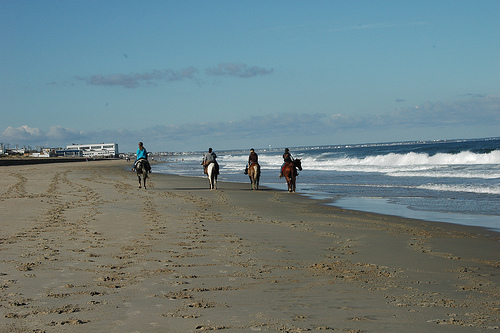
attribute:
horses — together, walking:
[130, 139, 309, 196]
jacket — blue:
[135, 145, 150, 161]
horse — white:
[201, 155, 221, 190]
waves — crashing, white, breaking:
[182, 150, 500, 198]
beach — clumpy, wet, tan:
[0, 136, 499, 332]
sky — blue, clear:
[0, 0, 500, 152]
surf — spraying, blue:
[134, 136, 500, 231]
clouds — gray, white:
[2, 13, 498, 148]